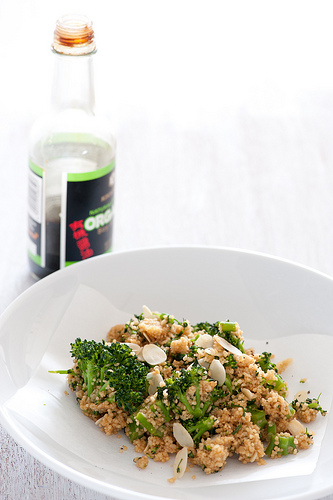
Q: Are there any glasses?
A: No, there are no glasses.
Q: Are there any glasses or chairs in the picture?
A: No, there are no glasses or chairs.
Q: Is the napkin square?
A: Yes, the napkin is square.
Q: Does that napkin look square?
A: Yes, the napkin is square.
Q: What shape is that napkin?
A: The napkin is square.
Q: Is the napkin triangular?
A: No, the napkin is square.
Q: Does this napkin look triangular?
A: No, the napkin is square.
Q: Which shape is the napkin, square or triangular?
A: The napkin is square.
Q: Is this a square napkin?
A: Yes, this is a square napkin.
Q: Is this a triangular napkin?
A: No, this is a square napkin.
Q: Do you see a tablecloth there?
A: No, there are no tablecloths.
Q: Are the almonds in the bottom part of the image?
A: Yes, the almonds are in the bottom of the image.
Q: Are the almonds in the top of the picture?
A: No, the almonds are in the bottom of the image.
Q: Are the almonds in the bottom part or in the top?
A: The almonds are in the bottom of the image.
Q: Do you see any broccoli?
A: Yes, there is broccoli.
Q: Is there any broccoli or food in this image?
A: Yes, there is broccoli.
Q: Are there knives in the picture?
A: No, there are no knives.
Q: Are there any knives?
A: No, there are no knives.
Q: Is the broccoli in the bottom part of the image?
A: Yes, the broccoli is in the bottom of the image.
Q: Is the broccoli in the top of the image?
A: No, the broccoli is in the bottom of the image.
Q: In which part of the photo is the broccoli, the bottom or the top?
A: The broccoli is in the bottom of the image.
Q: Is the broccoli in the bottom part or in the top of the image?
A: The broccoli is in the bottom of the image.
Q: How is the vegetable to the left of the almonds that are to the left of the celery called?
A: The vegetable is broccoli.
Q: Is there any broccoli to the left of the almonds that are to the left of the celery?
A: Yes, there is broccoli to the left of the almonds.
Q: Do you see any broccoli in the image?
A: Yes, there is broccoli.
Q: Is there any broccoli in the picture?
A: Yes, there is broccoli.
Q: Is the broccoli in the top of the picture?
A: No, the broccoli is in the bottom of the image.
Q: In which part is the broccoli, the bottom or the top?
A: The broccoli is in the bottom of the image.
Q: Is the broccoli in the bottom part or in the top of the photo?
A: The broccoli is in the bottom of the image.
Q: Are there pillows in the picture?
A: No, there are no pillows.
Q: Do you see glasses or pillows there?
A: No, there are no pillows or glasses.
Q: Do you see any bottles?
A: Yes, there is a bottle.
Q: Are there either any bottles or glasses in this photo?
A: Yes, there is a bottle.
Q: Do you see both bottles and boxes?
A: No, there is a bottle but no boxes.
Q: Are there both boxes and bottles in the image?
A: No, there is a bottle but no boxes.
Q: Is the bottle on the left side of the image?
A: Yes, the bottle is on the left of the image.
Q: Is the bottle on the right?
A: No, the bottle is on the left of the image.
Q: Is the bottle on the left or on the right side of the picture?
A: The bottle is on the left of the image.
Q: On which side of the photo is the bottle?
A: The bottle is on the left of the image.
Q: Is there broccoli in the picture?
A: Yes, there is broccoli.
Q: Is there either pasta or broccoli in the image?
A: Yes, there is broccoli.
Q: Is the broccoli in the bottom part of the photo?
A: Yes, the broccoli is in the bottom of the image.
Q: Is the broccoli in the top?
A: No, the broccoli is in the bottom of the image.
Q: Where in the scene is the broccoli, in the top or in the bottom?
A: The broccoli is in the bottom of the image.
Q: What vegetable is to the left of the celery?
A: The vegetable is broccoli.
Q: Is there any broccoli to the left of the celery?
A: Yes, there is broccoli to the left of the celery.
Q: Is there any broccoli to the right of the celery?
A: No, the broccoli is to the left of the celery.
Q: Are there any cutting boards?
A: No, there are no cutting boards.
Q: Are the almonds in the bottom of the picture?
A: Yes, the almonds are in the bottom of the image.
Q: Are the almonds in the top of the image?
A: No, the almonds are in the bottom of the image.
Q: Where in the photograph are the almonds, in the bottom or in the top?
A: The almonds are in the bottom of the image.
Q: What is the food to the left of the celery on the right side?
A: The food is almonds.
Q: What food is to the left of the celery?
A: The food is almonds.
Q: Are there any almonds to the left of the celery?
A: Yes, there are almonds to the left of the celery.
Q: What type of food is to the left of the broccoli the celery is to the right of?
A: The food is almonds.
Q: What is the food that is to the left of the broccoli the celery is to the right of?
A: The food is almonds.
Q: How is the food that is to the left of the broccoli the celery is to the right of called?
A: The food is almonds.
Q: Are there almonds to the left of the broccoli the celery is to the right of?
A: Yes, there are almonds to the left of the broccoli.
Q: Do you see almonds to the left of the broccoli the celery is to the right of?
A: Yes, there are almonds to the left of the broccoli.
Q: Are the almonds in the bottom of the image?
A: Yes, the almonds are in the bottom of the image.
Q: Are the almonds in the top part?
A: No, the almonds are in the bottom of the image.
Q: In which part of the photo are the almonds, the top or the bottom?
A: The almonds are in the bottom of the image.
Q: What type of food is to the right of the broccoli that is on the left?
A: The food is almonds.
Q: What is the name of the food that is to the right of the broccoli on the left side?
A: The food is almonds.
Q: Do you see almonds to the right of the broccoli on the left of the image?
A: Yes, there are almonds to the right of the broccoli.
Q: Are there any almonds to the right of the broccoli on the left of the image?
A: Yes, there are almonds to the right of the broccoli.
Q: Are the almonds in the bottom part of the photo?
A: Yes, the almonds are in the bottom of the image.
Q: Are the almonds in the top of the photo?
A: No, the almonds are in the bottom of the image.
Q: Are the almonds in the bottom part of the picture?
A: Yes, the almonds are in the bottom of the image.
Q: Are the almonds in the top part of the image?
A: No, the almonds are in the bottom of the image.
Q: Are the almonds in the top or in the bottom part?
A: The almonds are in the bottom of the image.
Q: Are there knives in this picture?
A: No, there are no knives.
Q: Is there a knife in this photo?
A: No, there are no knives.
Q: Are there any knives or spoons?
A: No, there are no knives or spoons.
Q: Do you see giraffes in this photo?
A: No, there are no giraffes.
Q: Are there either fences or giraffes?
A: No, there are no giraffes or fences.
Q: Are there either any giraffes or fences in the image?
A: No, there are no giraffes or fences.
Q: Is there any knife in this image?
A: No, there are no knives.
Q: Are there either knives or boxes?
A: No, there are no knives or boxes.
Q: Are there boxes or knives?
A: No, there are no knives or boxes.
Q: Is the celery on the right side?
A: Yes, the celery is on the right of the image.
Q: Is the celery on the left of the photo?
A: No, the celery is on the right of the image.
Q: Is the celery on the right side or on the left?
A: The celery is on the right of the image.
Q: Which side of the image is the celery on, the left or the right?
A: The celery is on the right of the image.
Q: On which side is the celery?
A: The celery is on the right of the image.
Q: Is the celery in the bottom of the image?
A: Yes, the celery is in the bottom of the image.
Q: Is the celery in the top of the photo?
A: No, the celery is in the bottom of the image.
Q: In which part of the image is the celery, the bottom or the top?
A: The celery is in the bottom of the image.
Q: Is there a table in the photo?
A: Yes, there is a table.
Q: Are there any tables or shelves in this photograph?
A: Yes, there is a table.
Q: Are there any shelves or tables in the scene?
A: Yes, there is a table.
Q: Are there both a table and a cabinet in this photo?
A: No, there is a table but no cabinets.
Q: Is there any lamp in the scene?
A: No, there are no lamps.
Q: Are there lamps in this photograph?
A: No, there are no lamps.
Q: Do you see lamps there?
A: No, there are no lamps.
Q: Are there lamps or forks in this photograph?
A: No, there are no lamps or forks.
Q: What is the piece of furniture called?
A: The piece of furniture is a table.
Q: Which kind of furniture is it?
A: The piece of furniture is a table.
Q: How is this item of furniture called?
A: That is a table.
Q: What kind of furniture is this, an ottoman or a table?
A: That is a table.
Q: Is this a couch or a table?
A: This is a table.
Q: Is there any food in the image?
A: Yes, there is food.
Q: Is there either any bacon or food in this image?
A: Yes, there is food.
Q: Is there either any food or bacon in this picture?
A: Yes, there is food.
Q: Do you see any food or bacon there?
A: Yes, there is food.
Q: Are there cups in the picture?
A: No, there are no cups.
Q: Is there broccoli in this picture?
A: Yes, there is broccoli.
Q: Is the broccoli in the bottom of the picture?
A: Yes, the broccoli is in the bottom of the image.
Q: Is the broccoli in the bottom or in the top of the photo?
A: The broccoli is in the bottom of the image.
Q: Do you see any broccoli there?
A: Yes, there is broccoli.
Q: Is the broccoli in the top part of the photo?
A: No, the broccoli is in the bottom of the image.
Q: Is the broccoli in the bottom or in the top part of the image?
A: The broccoli is in the bottom of the image.